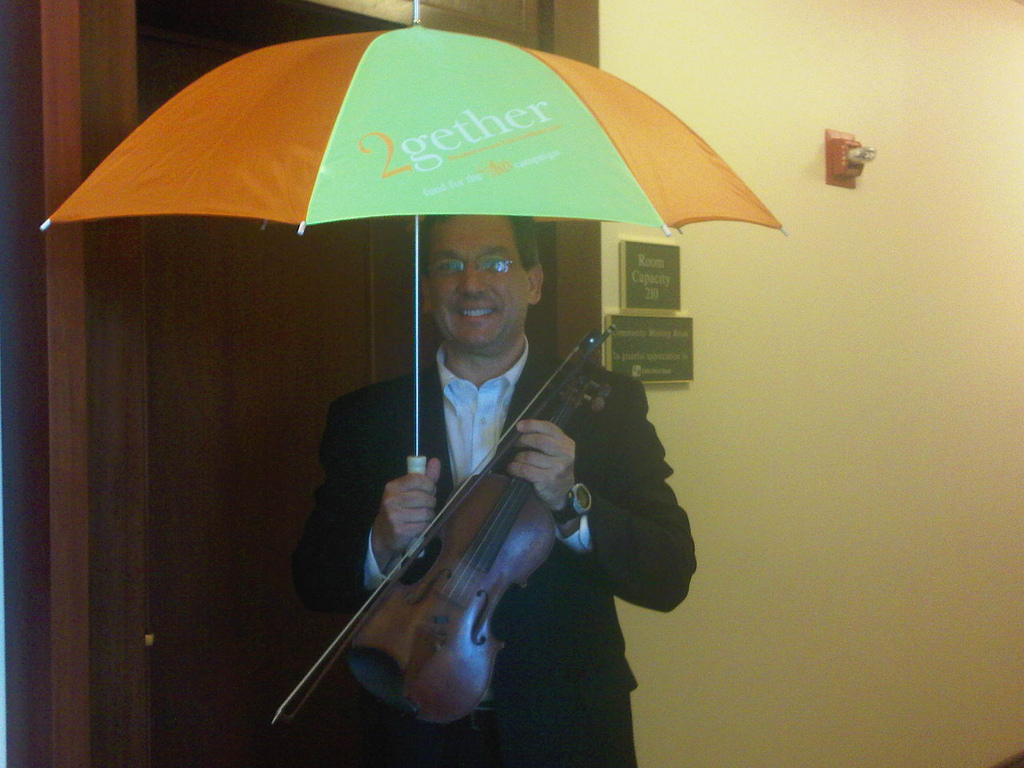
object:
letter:
[526, 101, 554, 124]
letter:
[429, 127, 462, 151]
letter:
[454, 121, 482, 144]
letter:
[504, 107, 538, 131]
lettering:
[614, 323, 693, 341]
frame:
[609, 240, 684, 320]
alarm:
[826, 128, 878, 190]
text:
[355, 96, 554, 181]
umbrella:
[31, 0, 794, 552]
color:
[50, 197, 301, 225]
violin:
[338, 365, 615, 731]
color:
[346, 646, 404, 710]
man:
[287, 214, 697, 768]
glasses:
[419, 255, 530, 278]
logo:
[354, 93, 551, 191]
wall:
[593, 0, 1024, 768]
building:
[0, 0, 1024, 768]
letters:
[354, 117, 571, 165]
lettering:
[630, 252, 671, 301]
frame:
[599, 314, 697, 386]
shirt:
[361, 325, 599, 594]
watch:
[546, 482, 594, 525]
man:
[197, 201, 693, 670]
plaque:
[619, 239, 686, 313]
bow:
[263, 320, 616, 727]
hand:
[502, 414, 577, 513]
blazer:
[287, 340, 700, 720]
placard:
[604, 314, 697, 386]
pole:
[406, 214, 426, 459]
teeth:
[454, 308, 493, 319]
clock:
[546, 480, 593, 526]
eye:
[432, 258, 465, 271]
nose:
[456, 263, 489, 298]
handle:
[397, 456, 432, 561]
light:
[788, 111, 895, 207]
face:
[426, 240, 527, 349]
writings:
[398, 134, 445, 173]